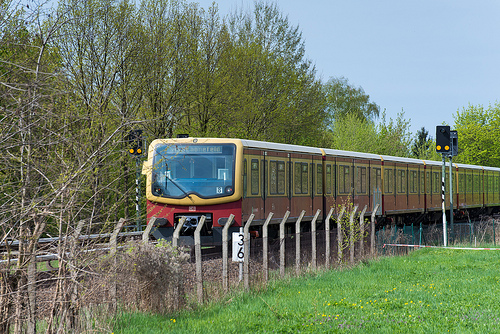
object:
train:
[146, 134, 500, 250]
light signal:
[434, 122, 452, 153]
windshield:
[153, 140, 239, 197]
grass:
[108, 244, 499, 334]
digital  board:
[164, 141, 225, 157]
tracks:
[2, 212, 500, 296]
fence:
[2, 202, 497, 333]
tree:
[211, 12, 323, 148]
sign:
[233, 231, 248, 265]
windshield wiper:
[162, 176, 197, 203]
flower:
[327, 299, 331, 309]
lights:
[442, 144, 450, 151]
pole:
[439, 160, 450, 249]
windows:
[257, 156, 291, 195]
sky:
[3, 3, 498, 139]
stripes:
[442, 178, 447, 210]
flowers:
[157, 272, 500, 333]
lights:
[134, 147, 143, 157]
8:
[217, 185, 223, 196]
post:
[192, 214, 206, 305]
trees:
[453, 108, 500, 169]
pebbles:
[5, 231, 357, 314]